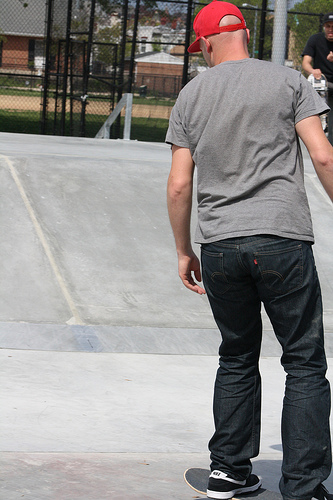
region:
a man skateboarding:
[158, 3, 331, 499]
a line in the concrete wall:
[9, 173, 97, 325]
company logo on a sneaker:
[204, 476, 222, 481]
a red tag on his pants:
[249, 255, 262, 268]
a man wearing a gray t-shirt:
[174, 9, 286, 490]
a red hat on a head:
[179, 0, 273, 48]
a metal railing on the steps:
[100, 95, 135, 136]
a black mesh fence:
[78, 14, 111, 80]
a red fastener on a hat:
[218, 23, 256, 31]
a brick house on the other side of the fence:
[0, 7, 86, 79]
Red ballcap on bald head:
[185, 3, 255, 54]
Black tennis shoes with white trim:
[194, 470, 273, 496]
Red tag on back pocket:
[249, 251, 264, 268]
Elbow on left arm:
[151, 174, 195, 207]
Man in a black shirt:
[304, 12, 331, 77]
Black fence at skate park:
[84, 13, 141, 84]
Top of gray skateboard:
[176, 464, 212, 488]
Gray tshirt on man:
[188, 81, 306, 213]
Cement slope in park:
[51, 148, 129, 342]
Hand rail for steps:
[97, 87, 142, 135]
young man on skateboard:
[151, 5, 325, 339]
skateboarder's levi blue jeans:
[205, 231, 319, 469]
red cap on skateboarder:
[185, 2, 263, 69]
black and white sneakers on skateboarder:
[201, 461, 272, 498]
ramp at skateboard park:
[42, 132, 177, 380]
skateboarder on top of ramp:
[298, 10, 331, 107]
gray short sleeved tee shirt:
[166, 48, 321, 257]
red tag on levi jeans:
[246, 254, 263, 268]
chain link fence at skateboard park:
[28, 17, 181, 116]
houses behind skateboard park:
[21, 13, 162, 70]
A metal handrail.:
[71, 87, 141, 154]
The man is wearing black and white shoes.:
[198, 464, 264, 495]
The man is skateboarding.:
[154, 8, 328, 493]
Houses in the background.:
[2, 1, 183, 118]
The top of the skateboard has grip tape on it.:
[181, 457, 325, 494]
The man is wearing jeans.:
[189, 234, 327, 486]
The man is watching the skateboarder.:
[299, 11, 328, 135]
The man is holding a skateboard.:
[297, 5, 326, 117]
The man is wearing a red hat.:
[174, 0, 252, 67]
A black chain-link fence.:
[11, 22, 84, 103]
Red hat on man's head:
[179, 4, 277, 71]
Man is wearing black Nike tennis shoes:
[199, 465, 305, 499]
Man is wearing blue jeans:
[175, 290, 330, 434]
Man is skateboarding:
[162, 254, 319, 498]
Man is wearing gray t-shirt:
[137, 53, 306, 229]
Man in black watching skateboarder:
[296, 18, 331, 99]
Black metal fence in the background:
[15, 9, 183, 91]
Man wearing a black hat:
[304, 12, 331, 61]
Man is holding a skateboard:
[306, 58, 327, 113]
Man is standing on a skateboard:
[183, 446, 320, 498]